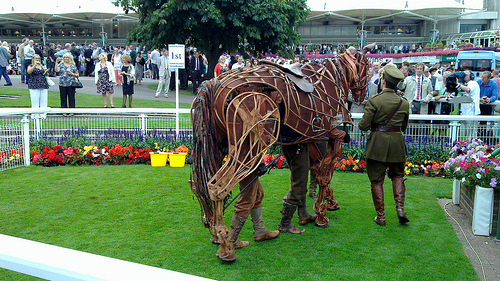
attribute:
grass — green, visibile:
[0, 83, 477, 280]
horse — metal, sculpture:
[187, 46, 373, 264]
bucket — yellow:
[149, 151, 169, 167]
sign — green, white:
[165, 43, 186, 72]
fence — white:
[1, 105, 499, 177]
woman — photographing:
[26, 54, 55, 118]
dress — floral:
[97, 65, 114, 93]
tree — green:
[110, 1, 309, 95]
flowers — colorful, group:
[2, 129, 500, 191]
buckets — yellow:
[150, 149, 188, 168]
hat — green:
[383, 63, 405, 87]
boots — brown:
[278, 197, 317, 236]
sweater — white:
[93, 60, 116, 84]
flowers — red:
[31, 143, 66, 166]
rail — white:
[2, 105, 190, 120]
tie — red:
[416, 76, 421, 101]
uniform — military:
[357, 63, 410, 227]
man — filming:
[456, 69, 482, 143]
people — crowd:
[2, 39, 500, 142]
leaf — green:
[256, 34, 261, 40]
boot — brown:
[370, 179, 388, 227]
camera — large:
[444, 72, 458, 95]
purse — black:
[70, 70, 83, 89]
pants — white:
[29, 87, 50, 120]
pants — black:
[59, 84, 77, 109]